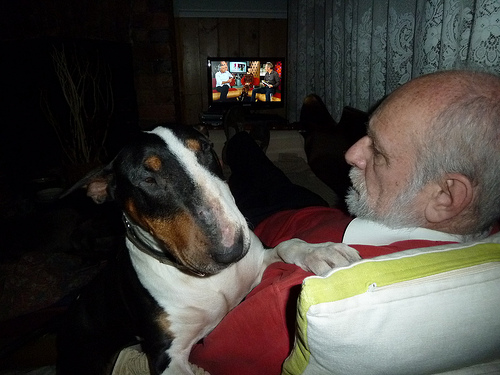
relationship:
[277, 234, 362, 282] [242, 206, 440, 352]
paw on shoulder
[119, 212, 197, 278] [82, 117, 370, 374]
collar on dog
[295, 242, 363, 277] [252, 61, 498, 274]
paw on man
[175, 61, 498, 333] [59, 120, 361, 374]
man sitting by dog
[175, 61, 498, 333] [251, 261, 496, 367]
man sitting on couch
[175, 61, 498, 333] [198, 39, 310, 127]
man watching tv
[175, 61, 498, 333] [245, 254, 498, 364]
man sitting on couch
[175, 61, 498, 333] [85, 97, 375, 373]
man looking at dog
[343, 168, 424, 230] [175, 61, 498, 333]
beard on man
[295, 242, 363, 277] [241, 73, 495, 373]
paw on man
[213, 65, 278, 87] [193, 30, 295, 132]
people on tv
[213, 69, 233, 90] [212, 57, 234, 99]
shirt on person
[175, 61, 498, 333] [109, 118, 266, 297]
man cuddling with dog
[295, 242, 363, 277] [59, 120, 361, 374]
paw on dog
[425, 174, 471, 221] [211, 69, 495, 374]
ear on man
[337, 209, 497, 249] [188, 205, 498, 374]
collar on shirt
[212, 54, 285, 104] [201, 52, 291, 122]
show playing on television